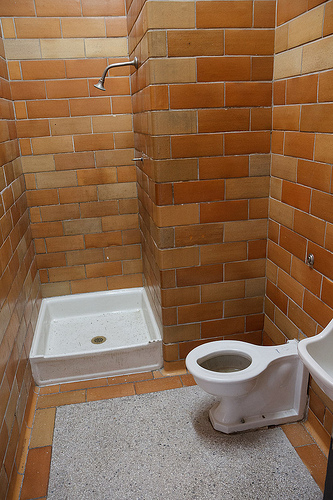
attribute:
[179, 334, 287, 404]
toilet seat — white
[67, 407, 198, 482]
floor — grey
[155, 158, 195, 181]
brick — brown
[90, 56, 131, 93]
wall mount — grey, silver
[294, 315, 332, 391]
sink — white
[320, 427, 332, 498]
pole — black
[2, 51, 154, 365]
shower — silver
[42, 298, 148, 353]
bottom — white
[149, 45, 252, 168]
wall — orange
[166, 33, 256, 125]
tiles — brown, tan